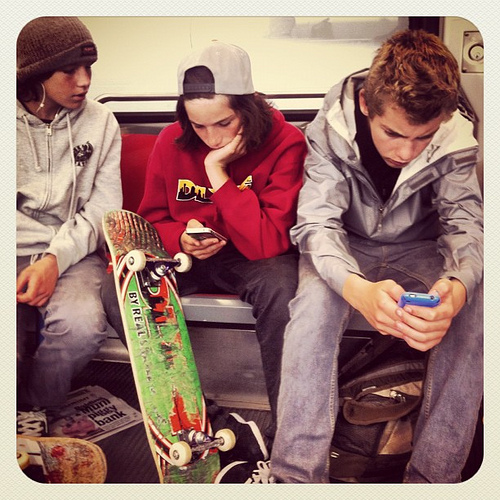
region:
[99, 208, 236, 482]
Multicolored skateboard leaning against a boy's knee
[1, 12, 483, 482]
Three kids sitting side by side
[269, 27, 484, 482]
A young man looking at a cellphone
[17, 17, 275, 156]
Two kids wearing different types of hats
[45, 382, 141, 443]
Part of a newspaper lying on the floor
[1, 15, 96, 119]
A kid wearing headphones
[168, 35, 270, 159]
A kid with his hat on backwards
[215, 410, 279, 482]
Black shoes with white laces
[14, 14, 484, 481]
Three young people sitting on a bench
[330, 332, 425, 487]
A bag sitting on the floor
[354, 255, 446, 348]
The boy holding the cellphone.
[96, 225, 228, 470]
Skateboard leaning on the boy leg.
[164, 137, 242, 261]
Boy is texting on the cellphone.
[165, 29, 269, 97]
The boy is wearing a cap.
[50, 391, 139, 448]
Newspaper on the ground.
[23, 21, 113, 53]
The person is wearing a hat.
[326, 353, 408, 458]
A backpack on the ground.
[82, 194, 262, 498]
a green skateboard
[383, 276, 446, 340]
a blue cellphone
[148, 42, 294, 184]
a boy wearing a backwards hat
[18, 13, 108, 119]
a boy wearing a brown hat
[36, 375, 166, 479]
a newspaper on the floor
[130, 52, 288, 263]
a boy on a cellphone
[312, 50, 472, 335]
a boy on a blue cellphone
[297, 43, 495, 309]
a boy wearing a silver jacket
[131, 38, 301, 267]
a boy wearing a red sweatshirt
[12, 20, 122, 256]
a boy wearing a gray sweatshirt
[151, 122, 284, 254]
boy with red sweater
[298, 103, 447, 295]
boy with grey jacket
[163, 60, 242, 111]
hat is backwards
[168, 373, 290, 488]
skateboard against knee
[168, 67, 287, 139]
hat is tan and black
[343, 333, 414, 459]
backpack behind the legs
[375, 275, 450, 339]
blue smartphone in hand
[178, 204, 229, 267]
silver smart phone in hand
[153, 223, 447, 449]
sitting on bus bench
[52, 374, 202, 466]
newspaper on the bus floor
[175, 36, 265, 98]
Gray snap-back hat on a person's head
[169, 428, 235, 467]
Skateboard truck with white wheels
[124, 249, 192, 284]
White wheels with a silver truck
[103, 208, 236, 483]
Underside of a skateboard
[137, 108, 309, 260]
A red sweater on a person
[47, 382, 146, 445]
Newspaper on the floor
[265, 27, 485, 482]
A boy in a silver jacket holding his phone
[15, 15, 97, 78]
A brown, knit cap on a head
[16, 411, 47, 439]
White laces on a black shor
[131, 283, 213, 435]
Faded design on the underside of a skateboard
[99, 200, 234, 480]
green skateboard with white wheels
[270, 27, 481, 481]
boy looking at blue phone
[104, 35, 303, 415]
boy wearing red shirt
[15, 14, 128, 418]
boy wearing brown hat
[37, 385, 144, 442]
white and black newspaper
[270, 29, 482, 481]
boy with short brown hair